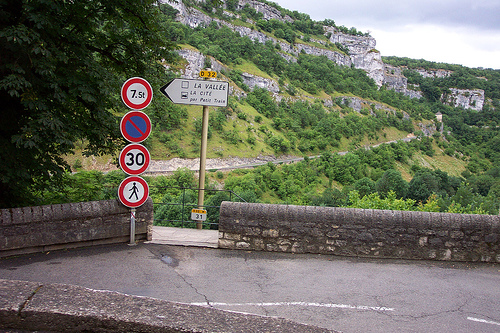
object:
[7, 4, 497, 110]
distance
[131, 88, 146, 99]
7.5t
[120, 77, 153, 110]
sign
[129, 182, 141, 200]
man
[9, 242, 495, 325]
street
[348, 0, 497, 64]
sky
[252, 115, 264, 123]
bushes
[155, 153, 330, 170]
road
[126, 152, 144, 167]
30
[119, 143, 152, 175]
sign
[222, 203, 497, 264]
fence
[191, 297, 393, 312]
stripes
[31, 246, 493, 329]
road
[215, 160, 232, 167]
rocks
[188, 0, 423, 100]
mountain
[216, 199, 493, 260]
wall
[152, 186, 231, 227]
rail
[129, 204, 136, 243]
pole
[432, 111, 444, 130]
buidling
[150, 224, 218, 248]
walkway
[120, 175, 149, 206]
signs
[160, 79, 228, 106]
sign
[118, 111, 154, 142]
sign